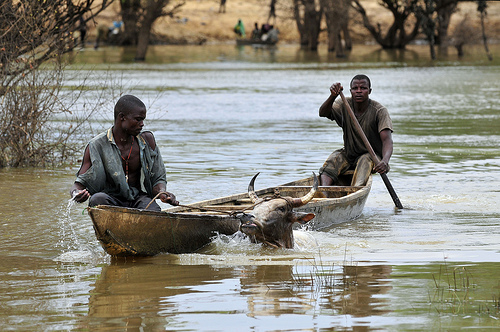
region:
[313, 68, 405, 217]
man rowing at back of kayak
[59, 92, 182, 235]
man at front of boat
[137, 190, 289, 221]
leash strapped to cow's head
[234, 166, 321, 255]
horned cow swimming in water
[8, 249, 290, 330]
murky brown lake water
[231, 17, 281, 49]
people loading into boat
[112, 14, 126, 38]
person wearing bright blue shirt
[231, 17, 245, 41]
person wearing bright green shirt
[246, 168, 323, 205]
horns on cow's head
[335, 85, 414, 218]
old wooden boat paddle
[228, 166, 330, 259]
a steer's head in the water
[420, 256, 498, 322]
grass protruding from water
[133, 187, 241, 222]
a brown leash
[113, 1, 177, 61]
trees protruding from water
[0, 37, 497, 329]
flood waters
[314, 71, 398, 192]
a man in a row boat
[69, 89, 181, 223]
a man wearing torn clothes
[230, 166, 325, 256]
a steer on a leash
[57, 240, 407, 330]
water reflection of men on a boat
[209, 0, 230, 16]
a person standing in grass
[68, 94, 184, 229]
a man holding a rope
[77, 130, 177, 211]
a ripped blue shirt on a man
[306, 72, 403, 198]
a man paddling a boat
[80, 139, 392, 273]
a boat on the water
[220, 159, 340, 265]
an ox in the water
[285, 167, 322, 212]
the horn of an ox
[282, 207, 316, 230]
the ear of an ox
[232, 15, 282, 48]
a group of people beside the water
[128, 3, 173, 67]
a tree in the water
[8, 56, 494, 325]
smooth river water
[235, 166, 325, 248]
a two horned steer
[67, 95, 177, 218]
a man riding in a boat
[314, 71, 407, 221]
a man steering a boat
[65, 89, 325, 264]
a man holding a steer on a leash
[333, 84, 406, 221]
a brown wooden oar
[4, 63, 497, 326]
a body of water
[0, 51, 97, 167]
a brush protruding from flood water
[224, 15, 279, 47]
people on the far shore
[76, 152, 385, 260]
an old canoe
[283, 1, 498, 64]
a grouping of trees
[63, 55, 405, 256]
two men in a boat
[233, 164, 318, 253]
a cow swimming in the river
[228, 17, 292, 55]
people on the river's edge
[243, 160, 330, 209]
the horns on a cow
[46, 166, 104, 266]
water splashing out of man's hand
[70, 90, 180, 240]
a man in a torn blue shirt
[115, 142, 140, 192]
a red necklace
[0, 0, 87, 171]
trees growing in the river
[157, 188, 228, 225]
the rope holding the cow